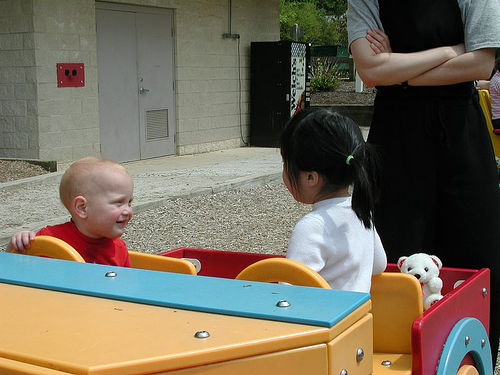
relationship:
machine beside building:
[231, 18, 347, 158] [80, 27, 279, 149]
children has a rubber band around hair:
[275, 108, 386, 297] [348, 165, 377, 227]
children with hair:
[275, 108, 386, 297] [280, 98, 402, 228]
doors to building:
[92, 3, 180, 158] [3, 0, 279, 169]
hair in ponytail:
[278, 106, 380, 226] [342, 144, 372, 231]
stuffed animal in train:
[396, 252, 443, 306] [0, 230, 495, 368]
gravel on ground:
[126, 177, 319, 249] [2, 123, 374, 251]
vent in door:
[140, 105, 178, 145] [93, 5, 193, 167]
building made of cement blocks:
[0, 0, 252, 176] [30, 62, 124, 179]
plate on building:
[54, 59, 86, 88] [3, 0, 279, 169]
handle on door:
[141, 70, 151, 96] [133, 11, 184, 158]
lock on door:
[140, 78, 147, 83] [133, 11, 184, 158]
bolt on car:
[277, 300, 289, 308] [2, 206, 494, 362]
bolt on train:
[277, 300, 289, 308] [7, 194, 497, 372]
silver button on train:
[5, 190, 493, 360] [8, 230, 496, 368]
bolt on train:
[195, 330, 209, 339] [0, 250, 497, 373]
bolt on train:
[105, 271, 116, 277] [0, 217, 496, 374]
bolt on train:
[195, 330, 209, 339] [5, 208, 472, 373]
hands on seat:
[8, 229, 34, 254] [6, 234, 85, 263]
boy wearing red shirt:
[6, 154, 138, 264] [34, 218, 130, 265]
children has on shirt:
[275, 108, 386, 297] [282, 198, 386, 294]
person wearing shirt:
[346, 3, 498, 363] [346, 1, 498, 49]